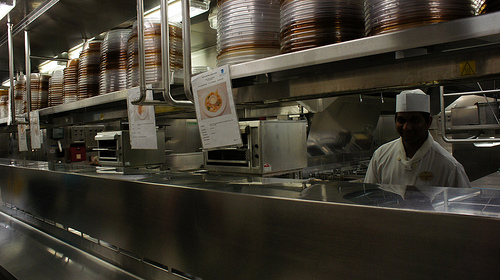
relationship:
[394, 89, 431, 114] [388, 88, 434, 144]
cap on head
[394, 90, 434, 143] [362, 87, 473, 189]
head of cook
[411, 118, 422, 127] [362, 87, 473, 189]
eye of cook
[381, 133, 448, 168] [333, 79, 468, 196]
neck of person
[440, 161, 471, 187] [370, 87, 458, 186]
arm of person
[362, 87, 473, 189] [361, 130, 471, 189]
cook wears shirt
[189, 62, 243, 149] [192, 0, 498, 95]
instructions stuck to shelf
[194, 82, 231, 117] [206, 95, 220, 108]
picture of plate of food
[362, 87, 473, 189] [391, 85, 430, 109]
cook has on a hat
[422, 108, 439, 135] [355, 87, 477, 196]
ear of a person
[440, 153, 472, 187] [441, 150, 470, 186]
arm of person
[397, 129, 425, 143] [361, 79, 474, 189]
mouth of person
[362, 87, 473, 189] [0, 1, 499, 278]
cook in kitchen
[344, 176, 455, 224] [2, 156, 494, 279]
reflection on steel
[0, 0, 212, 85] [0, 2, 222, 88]
lights are hanging from ceiling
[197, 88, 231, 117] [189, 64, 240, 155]
picture on sign